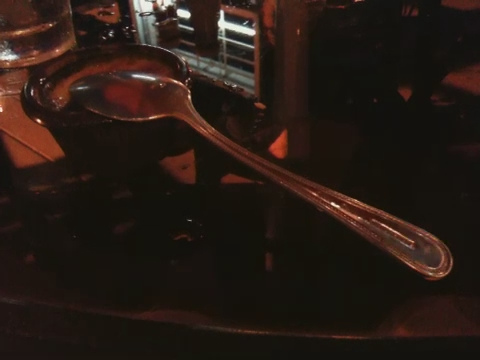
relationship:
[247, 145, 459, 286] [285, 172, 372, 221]
handle of spoon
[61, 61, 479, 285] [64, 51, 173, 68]
spoon resting on bowl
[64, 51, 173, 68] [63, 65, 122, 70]
bowl has sauce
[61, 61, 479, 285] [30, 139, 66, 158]
spoon on top of table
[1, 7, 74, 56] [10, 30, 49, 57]
water can has water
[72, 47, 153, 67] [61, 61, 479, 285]
cup with spoon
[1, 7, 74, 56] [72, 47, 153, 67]
water can near cup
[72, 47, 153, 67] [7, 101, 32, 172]
cup on top of dining table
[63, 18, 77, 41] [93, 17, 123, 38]
glass in corner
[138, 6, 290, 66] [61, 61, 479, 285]
display behind spoon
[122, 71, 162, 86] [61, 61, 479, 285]
reflection on spoon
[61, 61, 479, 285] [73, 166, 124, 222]
spoon resting on counter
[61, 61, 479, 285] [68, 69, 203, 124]
spoon has spoonhead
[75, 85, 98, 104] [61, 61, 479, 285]
tarnish on spoon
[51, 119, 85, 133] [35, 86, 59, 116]
edge of dish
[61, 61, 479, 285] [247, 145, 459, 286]
spoon has a handle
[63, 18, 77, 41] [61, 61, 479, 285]
glass in front of spoon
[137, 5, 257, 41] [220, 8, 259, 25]
window has frame